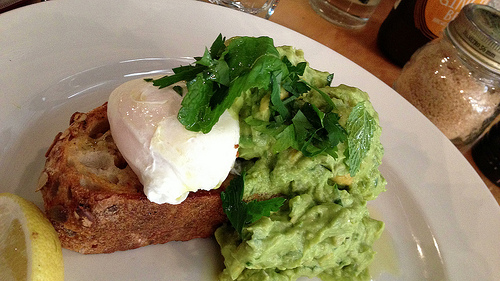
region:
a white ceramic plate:
[1, 0, 499, 278]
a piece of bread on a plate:
[36, 101, 228, 251]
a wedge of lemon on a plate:
[0, 191, 70, 279]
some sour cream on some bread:
[104, 74, 239, 202]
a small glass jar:
[390, 7, 499, 154]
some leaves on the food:
[141, 33, 377, 240]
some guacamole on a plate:
[216, 38, 390, 280]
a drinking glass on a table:
[207, 0, 280, 18]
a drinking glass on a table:
[310, 0, 377, 29]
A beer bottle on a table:
[374, 0, 486, 65]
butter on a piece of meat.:
[103, 54, 265, 226]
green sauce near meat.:
[174, 20, 407, 277]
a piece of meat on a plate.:
[20, 91, 250, 255]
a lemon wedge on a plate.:
[0, 162, 80, 279]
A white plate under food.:
[223, 8, 496, 279]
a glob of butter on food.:
[96, 72, 286, 222]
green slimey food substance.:
[310, 157, 369, 207]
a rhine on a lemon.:
[7, 198, 70, 275]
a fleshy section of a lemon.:
[5, 223, 30, 278]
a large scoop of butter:
[83, 70, 238, 232]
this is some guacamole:
[326, 114, 360, 225]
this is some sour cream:
[110, 112, 255, 198]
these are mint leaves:
[209, 29, 261, 121]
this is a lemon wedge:
[28, 192, 76, 271]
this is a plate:
[411, 223, 436, 271]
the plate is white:
[403, 185, 438, 234]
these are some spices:
[388, 24, 445, 86]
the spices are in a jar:
[396, 70, 496, 157]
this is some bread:
[75, 100, 132, 266]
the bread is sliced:
[19, 145, 120, 209]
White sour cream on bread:
[87, 43, 255, 213]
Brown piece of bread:
[37, 92, 264, 270]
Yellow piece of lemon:
[1, 186, 83, 278]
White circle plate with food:
[4, 1, 499, 278]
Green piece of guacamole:
[211, 46, 403, 279]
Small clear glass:
[314, 0, 379, 45]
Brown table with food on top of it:
[0, 1, 496, 210]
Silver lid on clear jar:
[443, 3, 499, 69]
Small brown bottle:
[367, 1, 483, 83]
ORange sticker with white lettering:
[412, 1, 472, 46]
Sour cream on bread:
[104, 82, 241, 207]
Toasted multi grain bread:
[25, 104, 232, 255]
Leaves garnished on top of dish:
[163, 29, 360, 164]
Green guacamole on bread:
[213, 37, 388, 279]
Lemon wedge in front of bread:
[0, 190, 66, 279]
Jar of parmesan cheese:
[395, 32, 499, 142]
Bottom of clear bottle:
[308, 1, 381, 33]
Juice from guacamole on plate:
[360, 211, 405, 276]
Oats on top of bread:
[30, 171, 55, 190]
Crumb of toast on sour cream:
[233, 141, 244, 158]